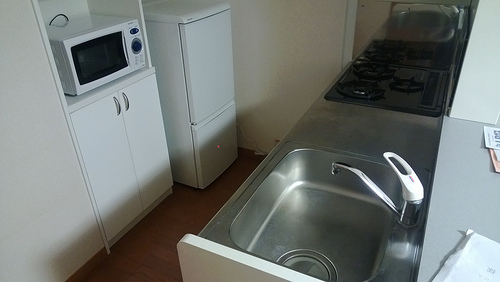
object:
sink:
[230, 148, 412, 282]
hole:
[285, 253, 329, 281]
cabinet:
[72, 76, 177, 241]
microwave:
[45, 16, 151, 94]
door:
[63, 31, 128, 82]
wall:
[231, 4, 346, 153]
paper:
[430, 229, 498, 282]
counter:
[416, 115, 498, 282]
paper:
[482, 125, 499, 151]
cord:
[49, 13, 70, 25]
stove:
[338, 77, 386, 99]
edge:
[175, 234, 331, 281]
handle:
[383, 151, 423, 201]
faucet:
[333, 149, 420, 227]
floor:
[66, 147, 267, 277]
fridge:
[146, 3, 238, 189]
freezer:
[190, 105, 240, 179]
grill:
[336, 78, 382, 100]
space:
[297, 101, 444, 162]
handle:
[114, 97, 122, 116]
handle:
[122, 92, 131, 111]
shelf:
[62, 66, 157, 111]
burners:
[388, 75, 428, 95]